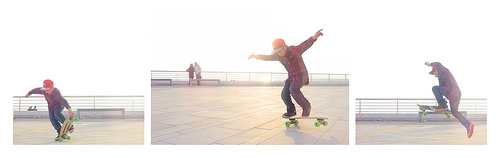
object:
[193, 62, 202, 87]
person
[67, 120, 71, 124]
wheel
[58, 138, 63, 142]
wheel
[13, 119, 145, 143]
concrete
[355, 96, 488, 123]
fence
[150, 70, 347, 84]
fence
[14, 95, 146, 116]
fence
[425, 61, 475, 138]
boy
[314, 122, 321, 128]
green wheel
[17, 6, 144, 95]
sky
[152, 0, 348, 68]
sky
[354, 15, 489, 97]
sky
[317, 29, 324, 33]
finger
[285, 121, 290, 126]
green wheel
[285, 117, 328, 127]
skate board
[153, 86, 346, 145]
floor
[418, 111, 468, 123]
bench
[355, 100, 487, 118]
gate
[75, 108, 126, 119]
bench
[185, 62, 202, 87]
couple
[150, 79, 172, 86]
bench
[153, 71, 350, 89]
gate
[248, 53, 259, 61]
hand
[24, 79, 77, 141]
boy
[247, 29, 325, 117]
boy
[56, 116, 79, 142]
skateboard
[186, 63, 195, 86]
person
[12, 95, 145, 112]
gate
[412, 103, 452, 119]
skate board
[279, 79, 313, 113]
jeans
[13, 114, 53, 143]
line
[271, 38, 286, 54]
cap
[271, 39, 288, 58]
head